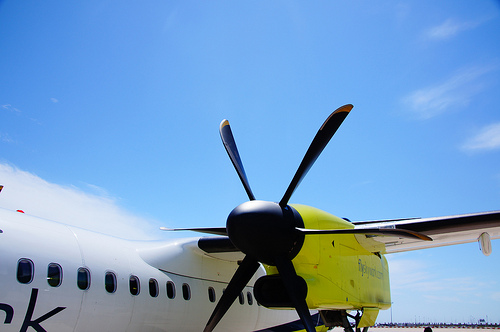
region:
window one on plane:
[12, 255, 39, 287]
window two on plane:
[41, 252, 68, 294]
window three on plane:
[73, 257, 94, 295]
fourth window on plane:
[96, 262, 125, 298]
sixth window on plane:
[138, 270, 164, 302]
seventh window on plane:
[158, 274, 180, 306]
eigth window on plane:
[178, 277, 195, 305]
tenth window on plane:
[236, 287, 249, 307]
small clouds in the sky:
[403, 16, 496, 148]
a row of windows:
[14, 258, 255, 305]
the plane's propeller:
[161, 101, 432, 330]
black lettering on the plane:
[0, 288, 65, 329]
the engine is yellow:
[278, 202, 391, 309]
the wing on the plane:
[176, 209, 498, 269]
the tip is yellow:
[213, 118, 232, 133]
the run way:
[337, 322, 497, 330]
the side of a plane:
[0, 104, 497, 329]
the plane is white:
[5, 205, 275, 330]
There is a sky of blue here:
[381, 153, 391, 185]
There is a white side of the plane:
[83, 235, 98, 258]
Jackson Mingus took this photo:
[151, 111, 238, 257]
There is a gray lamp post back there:
[383, 305, 395, 328]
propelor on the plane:
[142, 91, 398, 321]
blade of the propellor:
[271, 84, 389, 201]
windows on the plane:
[0, 245, 190, 311]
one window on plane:
[0, 236, 42, 301]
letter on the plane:
[23, 267, 77, 331]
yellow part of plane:
[275, 192, 386, 302]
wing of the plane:
[356, 185, 499, 254]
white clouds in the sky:
[411, 65, 498, 135]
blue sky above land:
[69, 47, 204, 155]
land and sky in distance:
[390, 288, 487, 330]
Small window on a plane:
[12, 249, 40, 290]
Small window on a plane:
[40, 258, 67, 290]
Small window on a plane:
[68, 254, 95, 297]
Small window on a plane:
[103, 266, 122, 296]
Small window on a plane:
[124, 274, 145, 297]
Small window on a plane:
[143, 273, 163, 305]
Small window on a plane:
[161, 273, 178, 298]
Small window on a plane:
[178, 276, 199, 303]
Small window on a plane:
[199, 276, 221, 302]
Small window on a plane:
[232, 288, 247, 308]